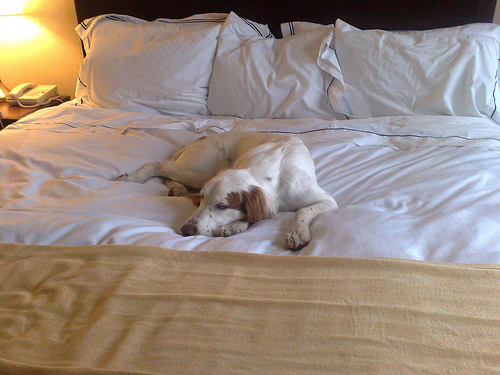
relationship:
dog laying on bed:
[110, 130, 338, 251] [0, 0, 499, 373]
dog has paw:
[110, 130, 338, 251] [285, 229, 313, 251]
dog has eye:
[110, 130, 338, 251] [216, 203, 230, 210]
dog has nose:
[110, 130, 338, 251] [181, 227, 198, 237]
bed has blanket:
[0, 0, 499, 373] [0, 242, 499, 374]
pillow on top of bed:
[74, 13, 229, 117] [0, 0, 499, 373]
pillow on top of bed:
[208, 9, 347, 122] [0, 0, 499, 373]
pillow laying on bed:
[334, 17, 499, 120] [0, 0, 499, 373]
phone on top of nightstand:
[6, 82, 65, 108] [0, 95, 70, 132]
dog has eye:
[110, 130, 338, 251] [200, 193, 206, 198]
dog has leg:
[110, 130, 338, 251] [116, 161, 182, 183]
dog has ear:
[110, 130, 338, 251] [243, 186, 271, 224]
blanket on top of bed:
[0, 242, 499, 374] [0, 0, 499, 373]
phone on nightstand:
[6, 82, 65, 108] [0, 95, 70, 132]